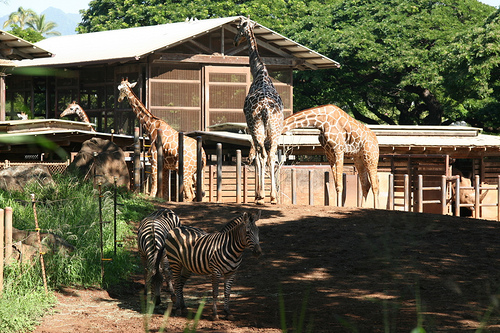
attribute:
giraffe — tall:
[280, 94, 401, 217]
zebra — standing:
[166, 212, 274, 317]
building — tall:
[34, 18, 323, 196]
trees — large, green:
[332, 5, 479, 104]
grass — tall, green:
[17, 196, 108, 261]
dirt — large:
[330, 227, 414, 286]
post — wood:
[211, 142, 249, 202]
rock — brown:
[60, 110, 137, 206]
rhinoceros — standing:
[442, 163, 491, 224]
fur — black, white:
[183, 230, 229, 265]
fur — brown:
[327, 121, 366, 150]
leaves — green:
[369, 19, 464, 104]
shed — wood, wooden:
[205, 133, 474, 208]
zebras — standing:
[128, 210, 262, 296]